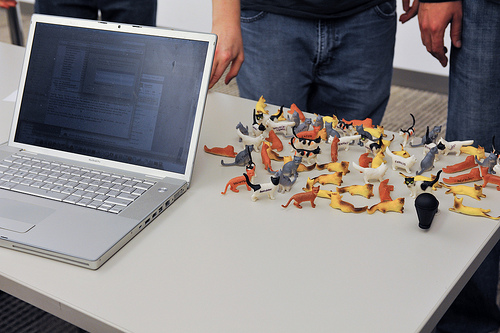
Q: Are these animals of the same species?
A: Yes, all the animals are cats.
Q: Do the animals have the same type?
A: Yes, all the animals are cats.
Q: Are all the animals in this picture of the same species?
A: Yes, all the animals are cats.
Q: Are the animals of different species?
A: No, all the animals are cats.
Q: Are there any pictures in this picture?
A: No, there are no pictures.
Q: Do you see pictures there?
A: No, there are no pictures.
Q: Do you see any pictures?
A: No, there are no pictures.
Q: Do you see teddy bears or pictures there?
A: No, there are no pictures or teddy bears.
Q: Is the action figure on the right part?
A: Yes, the action figure is on the right of the image.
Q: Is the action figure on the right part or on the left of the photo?
A: The action figure is on the right of the image.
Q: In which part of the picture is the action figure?
A: The action figure is on the right of the image.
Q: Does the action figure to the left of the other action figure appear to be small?
A: Yes, the action figure is small.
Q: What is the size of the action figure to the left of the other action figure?
A: The action figure is small.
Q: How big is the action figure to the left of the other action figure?
A: The action figure is small.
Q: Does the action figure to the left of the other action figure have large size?
A: No, the action figure is small.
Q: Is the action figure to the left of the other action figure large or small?
A: The action figure is small.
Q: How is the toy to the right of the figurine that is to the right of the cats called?
A: The toy is an action figure.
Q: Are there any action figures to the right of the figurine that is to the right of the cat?
A: Yes, there is an action figure to the right of the figurine.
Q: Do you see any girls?
A: No, there are no girls.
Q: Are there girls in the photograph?
A: No, there are no girls.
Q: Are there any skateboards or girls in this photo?
A: No, there are no girls or skateboards.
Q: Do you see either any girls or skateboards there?
A: No, there are no girls or skateboards.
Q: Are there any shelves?
A: No, there are no shelves.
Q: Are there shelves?
A: No, there are no shelves.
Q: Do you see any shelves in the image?
A: No, there are no shelves.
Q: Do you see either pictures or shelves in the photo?
A: No, there are no shelves or pictures.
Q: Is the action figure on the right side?
A: Yes, the action figure is on the right of the image.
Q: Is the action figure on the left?
A: No, the action figure is on the right of the image.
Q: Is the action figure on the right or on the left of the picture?
A: The action figure is on the right of the image.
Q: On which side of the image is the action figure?
A: The action figure is on the right of the image.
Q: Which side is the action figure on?
A: The action figure is on the right of the image.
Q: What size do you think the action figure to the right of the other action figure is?
A: The action figure is large.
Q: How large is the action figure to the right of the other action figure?
A: The action figure is large.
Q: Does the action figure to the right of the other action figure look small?
A: No, the action figure is large.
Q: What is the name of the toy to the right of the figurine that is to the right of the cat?
A: The toy is an action figure.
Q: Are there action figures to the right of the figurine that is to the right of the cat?
A: Yes, there is an action figure to the right of the figurine.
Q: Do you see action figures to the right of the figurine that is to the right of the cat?
A: Yes, there is an action figure to the right of the figurine.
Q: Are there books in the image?
A: No, there are no books.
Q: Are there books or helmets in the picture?
A: No, there are no books or helmets.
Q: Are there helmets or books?
A: No, there are no books or helmets.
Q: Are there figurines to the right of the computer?
A: Yes, there is a figurine to the right of the computer.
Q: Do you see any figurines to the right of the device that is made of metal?
A: Yes, there is a figurine to the right of the computer.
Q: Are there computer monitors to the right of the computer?
A: No, there is a figurine to the right of the computer.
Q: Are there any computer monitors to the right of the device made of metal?
A: No, there is a figurine to the right of the computer.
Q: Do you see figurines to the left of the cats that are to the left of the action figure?
A: Yes, there is a figurine to the left of the cats.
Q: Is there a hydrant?
A: No, there are no fire hydrants.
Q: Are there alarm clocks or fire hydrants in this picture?
A: No, there are no fire hydrants or alarm clocks.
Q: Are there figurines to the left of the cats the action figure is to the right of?
A: Yes, there is a figurine to the left of the cats.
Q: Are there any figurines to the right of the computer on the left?
A: Yes, there is a figurine to the right of the computer.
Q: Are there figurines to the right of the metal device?
A: Yes, there is a figurine to the right of the computer.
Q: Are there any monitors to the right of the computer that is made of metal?
A: No, there is a figurine to the right of the computer.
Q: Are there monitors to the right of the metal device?
A: No, there is a figurine to the right of the computer.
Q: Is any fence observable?
A: No, there are no fences.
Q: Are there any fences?
A: No, there are no fences.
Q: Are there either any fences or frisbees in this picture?
A: No, there are no fences or frisbees.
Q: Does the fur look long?
A: Yes, the fur is long.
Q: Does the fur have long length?
A: Yes, the fur is long.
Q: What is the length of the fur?
A: The fur is long.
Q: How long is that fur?
A: The fur is long.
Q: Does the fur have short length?
A: No, the fur is long.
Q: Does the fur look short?
A: No, the fur is long.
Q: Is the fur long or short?
A: The fur is long.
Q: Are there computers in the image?
A: Yes, there is a computer.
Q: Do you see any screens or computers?
A: Yes, there is a computer.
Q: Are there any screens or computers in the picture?
A: Yes, there is a computer.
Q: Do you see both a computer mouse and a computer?
A: No, there is a computer but no computer mice.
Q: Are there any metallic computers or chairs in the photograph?
A: Yes, there is a metal computer.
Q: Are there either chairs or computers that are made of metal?
A: Yes, the computer is made of metal.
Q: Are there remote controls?
A: No, there are no remote controls.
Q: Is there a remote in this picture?
A: No, there are no remote controls.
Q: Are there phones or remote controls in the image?
A: No, there are no remote controls or phones.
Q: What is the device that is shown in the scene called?
A: The device is a computer.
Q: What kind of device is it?
A: The device is a computer.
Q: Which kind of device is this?
A: This is a computer.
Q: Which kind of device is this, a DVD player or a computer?
A: This is a computer.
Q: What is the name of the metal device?
A: The device is a computer.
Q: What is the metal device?
A: The device is a computer.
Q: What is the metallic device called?
A: The device is a computer.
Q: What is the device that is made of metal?
A: The device is a computer.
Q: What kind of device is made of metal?
A: The device is a computer.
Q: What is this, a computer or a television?
A: This is a computer.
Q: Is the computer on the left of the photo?
A: Yes, the computer is on the left of the image.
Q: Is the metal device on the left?
A: Yes, the computer is on the left of the image.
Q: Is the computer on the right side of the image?
A: No, the computer is on the left of the image.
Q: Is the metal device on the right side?
A: No, the computer is on the left of the image.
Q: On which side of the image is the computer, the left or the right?
A: The computer is on the left of the image.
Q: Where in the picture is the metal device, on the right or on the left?
A: The computer is on the left of the image.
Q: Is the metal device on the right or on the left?
A: The computer is on the left of the image.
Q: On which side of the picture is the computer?
A: The computer is on the left of the image.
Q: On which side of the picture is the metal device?
A: The computer is on the left of the image.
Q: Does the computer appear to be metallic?
A: Yes, the computer is metallic.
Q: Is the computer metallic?
A: Yes, the computer is metallic.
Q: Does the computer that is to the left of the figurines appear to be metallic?
A: Yes, the computer is metallic.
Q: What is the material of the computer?
A: The computer is made of metal.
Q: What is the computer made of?
A: The computer is made of metal.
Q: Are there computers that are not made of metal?
A: No, there is a computer but it is made of metal.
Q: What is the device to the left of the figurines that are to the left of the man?
A: The device is a computer.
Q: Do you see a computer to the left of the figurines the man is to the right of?
A: Yes, there is a computer to the left of the figurines.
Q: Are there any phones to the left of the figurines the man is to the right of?
A: No, there is a computer to the left of the figurines.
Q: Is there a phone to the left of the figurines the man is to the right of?
A: No, there is a computer to the left of the figurines.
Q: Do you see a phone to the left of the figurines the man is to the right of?
A: No, there is a computer to the left of the figurines.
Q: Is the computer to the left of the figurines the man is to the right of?
A: Yes, the computer is to the left of the figurines.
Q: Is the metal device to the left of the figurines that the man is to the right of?
A: Yes, the computer is to the left of the figurines.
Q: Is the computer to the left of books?
A: No, the computer is to the left of the figurines.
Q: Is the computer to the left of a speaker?
A: No, the computer is to the left of a figurine.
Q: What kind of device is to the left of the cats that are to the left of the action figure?
A: The device is a computer.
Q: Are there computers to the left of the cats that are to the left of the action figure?
A: Yes, there is a computer to the left of the cats.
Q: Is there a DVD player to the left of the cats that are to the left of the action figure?
A: No, there is a computer to the left of the cats.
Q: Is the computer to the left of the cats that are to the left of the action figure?
A: Yes, the computer is to the left of the cats.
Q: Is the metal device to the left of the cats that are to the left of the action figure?
A: Yes, the computer is to the left of the cats.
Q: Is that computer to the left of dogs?
A: No, the computer is to the left of the cats.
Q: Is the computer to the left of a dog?
A: No, the computer is to the left of the cat.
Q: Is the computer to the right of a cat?
A: No, the computer is to the left of a cat.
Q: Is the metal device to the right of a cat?
A: No, the computer is to the left of a cat.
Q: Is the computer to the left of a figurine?
A: Yes, the computer is to the left of a figurine.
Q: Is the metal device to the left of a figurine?
A: Yes, the computer is to the left of a figurine.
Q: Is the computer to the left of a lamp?
A: No, the computer is to the left of a figurine.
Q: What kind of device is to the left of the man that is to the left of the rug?
A: The device is a computer.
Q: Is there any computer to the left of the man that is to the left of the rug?
A: Yes, there is a computer to the left of the man.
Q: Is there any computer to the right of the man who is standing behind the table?
A: No, the computer is to the left of the man.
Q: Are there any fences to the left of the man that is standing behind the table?
A: No, there is a computer to the left of the man.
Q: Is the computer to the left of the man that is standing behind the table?
A: Yes, the computer is to the left of the man.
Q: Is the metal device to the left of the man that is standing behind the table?
A: Yes, the computer is to the left of the man.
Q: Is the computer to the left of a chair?
A: No, the computer is to the left of the man.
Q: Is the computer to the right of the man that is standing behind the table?
A: No, the computer is to the left of the man.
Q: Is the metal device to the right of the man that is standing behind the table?
A: No, the computer is to the left of the man.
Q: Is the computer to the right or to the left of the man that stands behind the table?
A: The computer is to the left of the man.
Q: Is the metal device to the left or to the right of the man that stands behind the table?
A: The computer is to the left of the man.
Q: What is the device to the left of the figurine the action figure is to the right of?
A: The device is a computer.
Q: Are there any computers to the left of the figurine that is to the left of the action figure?
A: Yes, there is a computer to the left of the figurine.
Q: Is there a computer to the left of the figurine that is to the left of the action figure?
A: Yes, there is a computer to the left of the figurine.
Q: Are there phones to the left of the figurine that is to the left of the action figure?
A: No, there is a computer to the left of the figurine.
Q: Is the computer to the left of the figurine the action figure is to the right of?
A: Yes, the computer is to the left of the figurine.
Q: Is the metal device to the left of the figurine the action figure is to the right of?
A: Yes, the computer is to the left of the figurine.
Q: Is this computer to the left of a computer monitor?
A: No, the computer is to the left of the figurine.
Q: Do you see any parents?
A: No, there are no parents.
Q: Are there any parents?
A: No, there are no parents.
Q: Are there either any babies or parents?
A: No, there are no parents or babies.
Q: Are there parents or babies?
A: No, there are no parents or babies.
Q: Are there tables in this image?
A: Yes, there is a table.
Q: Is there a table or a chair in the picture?
A: Yes, there is a table.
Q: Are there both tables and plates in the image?
A: No, there is a table but no plates.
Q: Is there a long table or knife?
A: Yes, there is a long table.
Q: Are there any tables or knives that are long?
A: Yes, the table is long.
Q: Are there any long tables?
A: Yes, there is a long table.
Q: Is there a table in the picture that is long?
A: Yes, there is a table that is long.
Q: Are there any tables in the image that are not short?
A: Yes, there is a long table.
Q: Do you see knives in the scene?
A: No, there are no knives.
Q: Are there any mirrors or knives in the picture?
A: No, there are no knives or mirrors.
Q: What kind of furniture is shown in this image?
A: The furniture is a table.